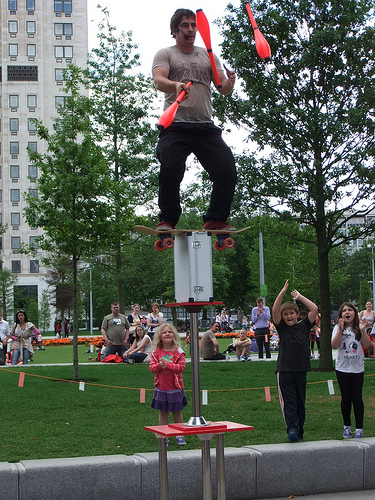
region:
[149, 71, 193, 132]
bright orange juggling pin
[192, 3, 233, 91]
bright orange juggling pin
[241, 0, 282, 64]
bright orange juggling pin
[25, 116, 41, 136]
window on a building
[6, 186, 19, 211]
window on a building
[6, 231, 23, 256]
window on a building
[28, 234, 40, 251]
window on a building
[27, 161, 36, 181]
window on a building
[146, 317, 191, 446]
person watching the juggler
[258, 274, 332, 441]
person watching the juggler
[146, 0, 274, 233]
A man juggling pins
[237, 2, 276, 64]
A red pin in the air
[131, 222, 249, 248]
A skateboard under the man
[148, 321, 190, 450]
A child standing in the grass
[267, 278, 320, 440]
A boy in a black shirt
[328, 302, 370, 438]
A girl standing in the grass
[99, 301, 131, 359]
A man with his hands in his pocket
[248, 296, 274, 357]
A man in a light purple shirt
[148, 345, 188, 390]
A pink shirt and jacket on the girl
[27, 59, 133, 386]
A slim deciduous tree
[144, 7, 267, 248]
man juggling three pins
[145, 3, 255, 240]
man balancing on skateboard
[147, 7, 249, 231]
man wearing red shoes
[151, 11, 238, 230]
man wearing black pants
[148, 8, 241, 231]
man wearing tan shirt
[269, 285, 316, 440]
boy wearing black shoes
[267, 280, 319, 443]
boy wearing black pants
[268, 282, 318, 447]
boy wearing black shirt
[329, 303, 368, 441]
girl wearing black pants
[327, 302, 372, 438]
girl wearing white shirt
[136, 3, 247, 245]
man standing on a skateboard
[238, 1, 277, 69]
red and black bowling pin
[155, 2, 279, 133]
man juggling three bowling pins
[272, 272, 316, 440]
young boy wearing a black shirt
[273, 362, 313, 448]
long black pants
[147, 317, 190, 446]
young girl wearing purple skirt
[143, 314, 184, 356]
girl with blond hair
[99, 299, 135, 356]
man wearing brown shirt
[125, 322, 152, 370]
woman sitting on the grass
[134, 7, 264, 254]
man standing on a sakteboard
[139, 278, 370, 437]
three kids standing on the gras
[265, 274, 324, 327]
hands are above the head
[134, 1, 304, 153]
man is juggling pins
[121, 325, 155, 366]
woman sitting on the sidewalk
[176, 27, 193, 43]
black microphone sitting on the face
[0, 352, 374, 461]
green grass on the ground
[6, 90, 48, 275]
windows on the side of the building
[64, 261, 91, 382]
skinny brown tree trunk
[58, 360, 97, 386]
tree trunk sticking out of the dirt